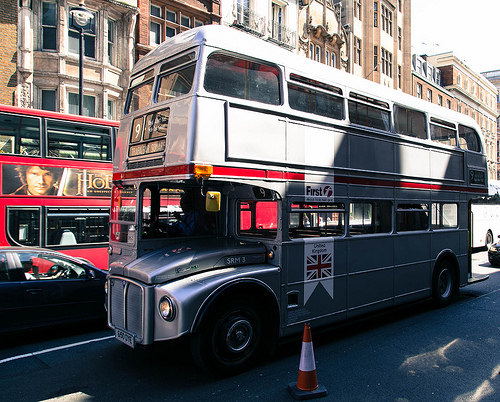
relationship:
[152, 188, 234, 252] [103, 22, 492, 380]
driver of bus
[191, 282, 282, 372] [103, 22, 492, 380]
wheel on bus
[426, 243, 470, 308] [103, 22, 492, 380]
wheel on bus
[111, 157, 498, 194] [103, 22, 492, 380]
stripe on bus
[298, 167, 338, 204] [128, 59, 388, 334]
sign on side of bus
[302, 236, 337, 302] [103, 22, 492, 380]
flag on side of bus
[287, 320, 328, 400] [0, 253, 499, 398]
cone on road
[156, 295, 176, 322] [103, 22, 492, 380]
headlamp on bus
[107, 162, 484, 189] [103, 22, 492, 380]
stripe on side of bus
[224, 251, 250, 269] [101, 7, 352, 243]
number on side of bus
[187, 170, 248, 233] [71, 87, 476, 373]
mirror on bus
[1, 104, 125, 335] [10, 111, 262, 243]
bus between buses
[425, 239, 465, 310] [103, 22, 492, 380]
wheel on bus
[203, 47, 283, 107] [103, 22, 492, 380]
top window on bus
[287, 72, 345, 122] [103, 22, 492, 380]
top window on bus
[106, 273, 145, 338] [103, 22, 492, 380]
grill on bus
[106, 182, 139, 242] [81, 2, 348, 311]
windshield on bus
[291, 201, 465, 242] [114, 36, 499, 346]
windows on bus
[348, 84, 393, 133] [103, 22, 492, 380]
top window on bus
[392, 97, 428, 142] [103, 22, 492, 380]
top window on bus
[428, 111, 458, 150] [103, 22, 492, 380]
top window on bus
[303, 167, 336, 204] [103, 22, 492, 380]
poster on bus